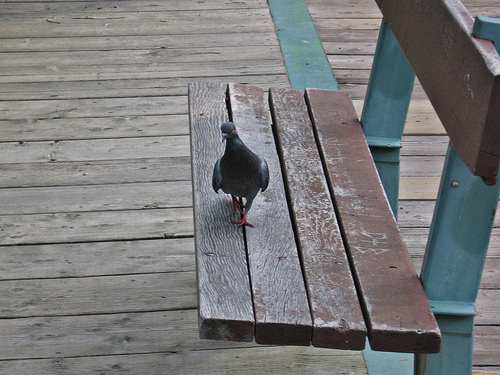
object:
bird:
[211, 122, 271, 229]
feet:
[230, 212, 255, 228]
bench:
[186, 0, 496, 355]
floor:
[5, 3, 199, 374]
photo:
[0, 0, 500, 375]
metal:
[415, 199, 498, 374]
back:
[378, 1, 499, 187]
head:
[220, 122, 237, 143]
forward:
[193, 106, 292, 324]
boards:
[451, 48, 490, 174]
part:
[324, 8, 370, 56]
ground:
[316, 2, 374, 46]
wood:
[184, 82, 442, 354]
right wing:
[258, 157, 270, 193]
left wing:
[212, 158, 223, 194]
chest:
[222, 153, 257, 186]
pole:
[413, 144, 500, 373]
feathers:
[237, 152, 259, 192]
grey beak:
[221, 134, 227, 143]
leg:
[244, 197, 252, 214]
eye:
[231, 128, 235, 131]